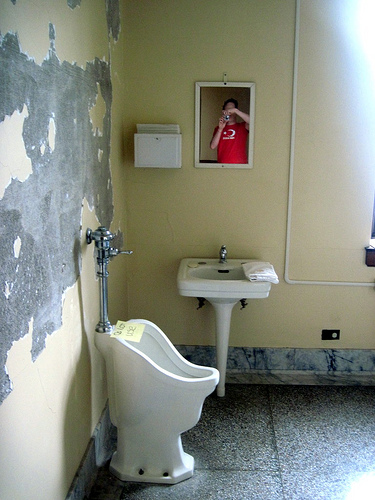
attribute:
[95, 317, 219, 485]
urinal — white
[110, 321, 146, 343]
sign — yellow, out of order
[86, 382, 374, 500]
floor — tiled, speckled, gray, dark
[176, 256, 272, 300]
sink — small, white, empty, pedestal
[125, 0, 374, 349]
wall — light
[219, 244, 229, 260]
faucet — silver, metal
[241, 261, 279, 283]
towel — white, folded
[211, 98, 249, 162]
reflection — man, photographer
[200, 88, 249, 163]
mirror — framed, mounted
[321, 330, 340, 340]
outlet — electrical, covered, bottom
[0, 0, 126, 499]
wall — chipped, peeled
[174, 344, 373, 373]
baseboard — marble, faux marble, wide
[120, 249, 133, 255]
handle — silver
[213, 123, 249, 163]
shirt — red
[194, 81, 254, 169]
frame — white